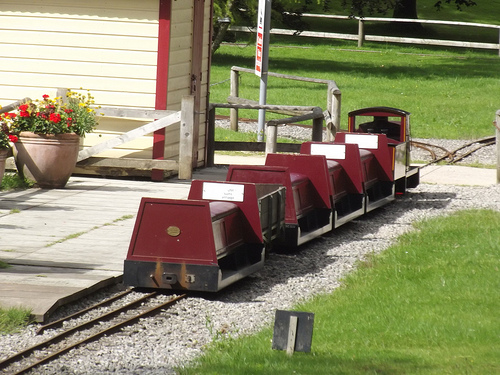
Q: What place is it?
A: It is a garden.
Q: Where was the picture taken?
A: It was taken at the garden.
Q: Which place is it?
A: It is a garden.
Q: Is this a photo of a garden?
A: Yes, it is showing a garden.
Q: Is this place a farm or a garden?
A: It is a garden.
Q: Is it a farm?
A: No, it is a garden.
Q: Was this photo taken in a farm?
A: No, the picture was taken in a garden.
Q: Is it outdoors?
A: Yes, it is outdoors.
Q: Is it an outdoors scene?
A: Yes, it is outdoors.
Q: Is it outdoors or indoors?
A: It is outdoors.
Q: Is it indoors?
A: No, it is outdoors.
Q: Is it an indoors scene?
A: No, it is outdoors.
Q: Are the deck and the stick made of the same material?
A: Yes, both the deck and the stick are made of wood.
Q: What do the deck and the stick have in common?
A: The material, both the deck and the stick are wooden.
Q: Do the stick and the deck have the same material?
A: Yes, both the stick and the deck are made of wood.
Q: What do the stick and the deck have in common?
A: The material, both the stick and the deck are wooden.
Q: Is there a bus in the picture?
A: No, there are no buses.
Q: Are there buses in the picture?
A: No, there are no buses.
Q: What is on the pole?
A: The sign is on the pole.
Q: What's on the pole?
A: The sign is on the pole.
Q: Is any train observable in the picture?
A: Yes, there is a train.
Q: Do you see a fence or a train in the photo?
A: Yes, there is a train.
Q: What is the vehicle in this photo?
A: The vehicle is a train.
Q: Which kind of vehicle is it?
A: The vehicle is a train.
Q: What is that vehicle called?
A: This is a train.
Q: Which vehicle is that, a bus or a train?
A: This is a train.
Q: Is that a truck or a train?
A: That is a train.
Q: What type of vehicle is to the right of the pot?
A: The vehicle is a train.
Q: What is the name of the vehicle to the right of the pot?
A: The vehicle is a train.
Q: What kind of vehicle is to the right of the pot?
A: The vehicle is a train.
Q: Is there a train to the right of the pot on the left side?
A: Yes, there is a train to the right of the pot.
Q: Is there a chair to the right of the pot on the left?
A: No, there is a train to the right of the pot.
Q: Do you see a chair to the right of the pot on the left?
A: No, there is a train to the right of the pot.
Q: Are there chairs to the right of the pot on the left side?
A: No, there is a train to the right of the pot.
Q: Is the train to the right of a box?
A: No, the train is to the right of the pot.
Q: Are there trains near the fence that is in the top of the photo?
A: Yes, there is a train near the fence.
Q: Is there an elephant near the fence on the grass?
A: No, there is a train near the fence.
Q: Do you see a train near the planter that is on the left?
A: Yes, there is a train near the planter.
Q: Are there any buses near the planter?
A: No, there is a train near the planter.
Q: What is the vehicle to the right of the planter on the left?
A: The vehicle is a train.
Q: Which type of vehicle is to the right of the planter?
A: The vehicle is a train.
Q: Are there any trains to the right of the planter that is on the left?
A: Yes, there is a train to the right of the planter.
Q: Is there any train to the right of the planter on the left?
A: Yes, there is a train to the right of the planter.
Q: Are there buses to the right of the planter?
A: No, there is a train to the right of the planter.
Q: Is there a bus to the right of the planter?
A: No, there is a train to the right of the planter.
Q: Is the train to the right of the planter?
A: Yes, the train is to the right of the planter.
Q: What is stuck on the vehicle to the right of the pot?
A: The sign is stuck on the train.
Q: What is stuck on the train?
A: The sign is stuck on the train.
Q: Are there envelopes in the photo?
A: No, there are no envelopes.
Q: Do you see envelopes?
A: No, there are no envelopes.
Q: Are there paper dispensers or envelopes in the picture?
A: No, there are no envelopes or paper dispensers.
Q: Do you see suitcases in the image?
A: No, there are no suitcases.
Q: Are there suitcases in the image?
A: No, there are no suitcases.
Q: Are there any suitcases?
A: No, there are no suitcases.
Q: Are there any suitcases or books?
A: No, there are no suitcases or books.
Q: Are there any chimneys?
A: No, there are no chimneys.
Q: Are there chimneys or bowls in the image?
A: No, there are no chimneys or bowls.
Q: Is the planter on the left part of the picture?
A: Yes, the planter is on the left of the image.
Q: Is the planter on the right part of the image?
A: No, the planter is on the left of the image.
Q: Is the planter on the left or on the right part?
A: The planter is on the left of the image.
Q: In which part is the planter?
A: The planter is on the left of the image.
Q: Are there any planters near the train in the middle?
A: Yes, there is a planter near the train.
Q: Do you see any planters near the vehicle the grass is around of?
A: Yes, there is a planter near the train.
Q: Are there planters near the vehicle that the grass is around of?
A: Yes, there is a planter near the train.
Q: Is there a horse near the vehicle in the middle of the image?
A: No, there is a planter near the train.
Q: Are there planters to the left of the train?
A: Yes, there is a planter to the left of the train.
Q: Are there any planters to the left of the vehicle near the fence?
A: Yes, there is a planter to the left of the train.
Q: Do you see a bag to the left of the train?
A: No, there is a planter to the left of the train.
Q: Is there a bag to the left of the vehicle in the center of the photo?
A: No, there is a planter to the left of the train.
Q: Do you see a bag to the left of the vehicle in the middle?
A: No, there is a planter to the left of the train.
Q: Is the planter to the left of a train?
A: Yes, the planter is to the left of a train.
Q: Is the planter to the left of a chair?
A: No, the planter is to the left of a train.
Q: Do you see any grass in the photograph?
A: Yes, there is grass.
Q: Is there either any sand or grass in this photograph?
A: Yes, there is grass.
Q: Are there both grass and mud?
A: No, there is grass but no mud.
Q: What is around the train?
A: The grass is around the train.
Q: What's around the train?
A: The grass is around the train.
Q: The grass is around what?
A: The grass is around the train.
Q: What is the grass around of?
A: The grass is around the train.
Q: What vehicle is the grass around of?
A: The grass is around the train.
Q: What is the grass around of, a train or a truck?
A: The grass is around a train.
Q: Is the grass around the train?
A: Yes, the grass is around the train.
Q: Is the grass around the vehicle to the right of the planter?
A: Yes, the grass is around the train.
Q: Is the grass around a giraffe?
A: No, the grass is around the train.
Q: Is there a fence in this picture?
A: Yes, there is a fence.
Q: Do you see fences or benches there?
A: Yes, there is a fence.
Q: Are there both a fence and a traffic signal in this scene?
A: No, there is a fence but no traffic lights.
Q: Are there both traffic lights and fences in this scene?
A: No, there is a fence but no traffic lights.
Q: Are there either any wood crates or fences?
A: Yes, there is a wood fence.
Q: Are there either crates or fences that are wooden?
A: Yes, the fence is wooden.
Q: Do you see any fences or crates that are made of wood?
A: Yes, the fence is made of wood.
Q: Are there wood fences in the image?
A: Yes, there is a wood fence.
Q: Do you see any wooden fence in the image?
A: Yes, there is a wood fence.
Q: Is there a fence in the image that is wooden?
A: Yes, there is a fence that is wooden.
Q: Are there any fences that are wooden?
A: Yes, there is a fence that is wooden.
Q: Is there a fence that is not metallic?
A: Yes, there is a wooden fence.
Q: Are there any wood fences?
A: Yes, there is a fence that is made of wood.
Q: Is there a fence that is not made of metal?
A: Yes, there is a fence that is made of wood.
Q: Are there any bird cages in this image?
A: No, there are no bird cages.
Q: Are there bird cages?
A: No, there are no bird cages.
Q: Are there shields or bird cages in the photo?
A: No, there are no bird cages or shields.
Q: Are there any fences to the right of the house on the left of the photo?
A: Yes, there is a fence to the right of the house.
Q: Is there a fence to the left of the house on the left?
A: No, the fence is to the right of the house.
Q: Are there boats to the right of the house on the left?
A: No, there is a fence to the right of the house.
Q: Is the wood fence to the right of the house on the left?
A: Yes, the fence is to the right of the house.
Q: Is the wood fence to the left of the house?
A: No, the fence is to the right of the house.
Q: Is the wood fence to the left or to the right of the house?
A: The fence is to the right of the house.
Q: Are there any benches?
A: Yes, there is a bench.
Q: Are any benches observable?
A: Yes, there is a bench.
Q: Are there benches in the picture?
A: Yes, there is a bench.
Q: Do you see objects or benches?
A: Yes, there is a bench.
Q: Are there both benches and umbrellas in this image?
A: No, there is a bench but no umbrellas.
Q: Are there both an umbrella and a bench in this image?
A: No, there is a bench but no umbrellas.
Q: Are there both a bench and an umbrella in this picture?
A: No, there is a bench but no umbrellas.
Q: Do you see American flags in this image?
A: No, there are no American flags.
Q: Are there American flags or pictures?
A: No, there are no American flags or pictures.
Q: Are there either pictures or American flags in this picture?
A: No, there are no American flags or pictures.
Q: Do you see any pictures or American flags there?
A: No, there are no American flags or pictures.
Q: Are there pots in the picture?
A: Yes, there is a pot.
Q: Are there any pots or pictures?
A: Yes, there is a pot.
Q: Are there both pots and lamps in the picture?
A: No, there is a pot but no lamps.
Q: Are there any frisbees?
A: No, there are no frisbees.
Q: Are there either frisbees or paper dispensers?
A: No, there are no frisbees or paper dispensers.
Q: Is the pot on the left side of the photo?
A: Yes, the pot is on the left of the image.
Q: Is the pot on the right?
A: No, the pot is on the left of the image.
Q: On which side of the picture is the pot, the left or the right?
A: The pot is on the left of the image.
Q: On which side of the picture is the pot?
A: The pot is on the left of the image.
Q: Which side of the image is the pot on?
A: The pot is on the left of the image.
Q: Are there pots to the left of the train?
A: Yes, there is a pot to the left of the train.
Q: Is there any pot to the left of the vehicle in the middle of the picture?
A: Yes, there is a pot to the left of the train.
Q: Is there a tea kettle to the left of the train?
A: No, there is a pot to the left of the train.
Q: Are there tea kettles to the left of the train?
A: No, there is a pot to the left of the train.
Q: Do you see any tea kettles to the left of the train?
A: No, there is a pot to the left of the train.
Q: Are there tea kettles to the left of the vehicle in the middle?
A: No, there is a pot to the left of the train.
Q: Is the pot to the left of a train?
A: Yes, the pot is to the left of a train.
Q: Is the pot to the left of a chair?
A: No, the pot is to the left of a train.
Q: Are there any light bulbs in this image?
A: No, there are no light bulbs.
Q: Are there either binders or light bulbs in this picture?
A: No, there are no light bulbs or binders.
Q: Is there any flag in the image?
A: No, there are no flags.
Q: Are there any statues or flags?
A: No, there are no flags or statues.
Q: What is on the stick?
A: The sign is on the stick.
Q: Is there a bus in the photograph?
A: No, there are no buses.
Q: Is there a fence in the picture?
A: Yes, there is a fence.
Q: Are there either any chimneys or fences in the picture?
A: Yes, there is a fence.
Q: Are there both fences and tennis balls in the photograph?
A: No, there is a fence but no tennis balls.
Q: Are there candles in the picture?
A: No, there are no candles.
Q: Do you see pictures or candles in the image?
A: No, there are no candles or pictures.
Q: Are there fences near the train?
A: Yes, there is a fence near the train.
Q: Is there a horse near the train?
A: No, there is a fence near the train.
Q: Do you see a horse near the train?
A: No, there is a fence near the train.